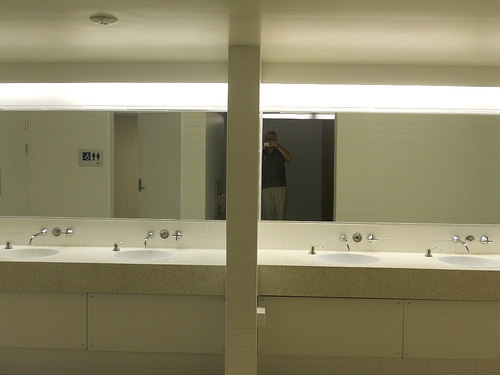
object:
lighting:
[0, 82, 500, 119]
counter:
[0, 246, 500, 373]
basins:
[0, 246, 499, 270]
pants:
[261, 187, 286, 220]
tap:
[367, 232, 378, 240]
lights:
[0, 82, 495, 119]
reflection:
[262, 112, 500, 222]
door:
[138, 113, 180, 218]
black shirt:
[261, 144, 287, 188]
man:
[261, 130, 292, 220]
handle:
[138, 179, 145, 191]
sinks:
[0, 246, 500, 266]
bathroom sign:
[79, 150, 103, 166]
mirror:
[0, 109, 499, 225]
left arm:
[276, 145, 292, 161]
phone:
[264, 142, 270, 146]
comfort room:
[0, 0, 500, 375]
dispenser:
[310, 246, 316, 254]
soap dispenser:
[5, 238, 15, 250]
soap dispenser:
[114, 241, 123, 251]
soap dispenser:
[310, 241, 324, 254]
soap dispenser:
[425, 246, 442, 257]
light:
[0, 82, 500, 120]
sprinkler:
[88, 13, 118, 26]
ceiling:
[1, 0, 500, 63]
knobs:
[52, 226, 62, 236]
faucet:
[28, 229, 48, 246]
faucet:
[143, 230, 155, 248]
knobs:
[353, 232, 362, 242]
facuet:
[342, 236, 352, 251]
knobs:
[466, 235, 474, 243]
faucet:
[451, 236, 471, 255]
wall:
[0, 61, 500, 375]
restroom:
[0, 0, 500, 375]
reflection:
[0, 111, 225, 220]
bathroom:
[4, 3, 498, 372]